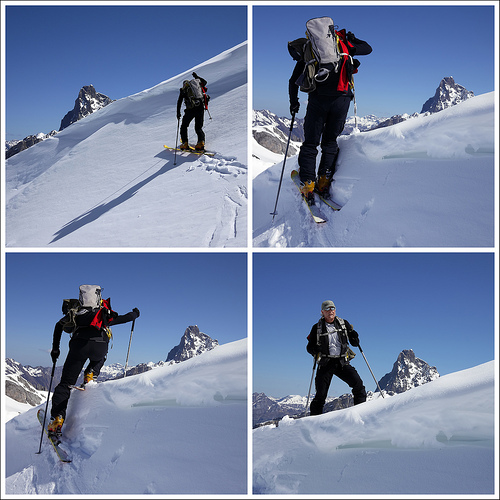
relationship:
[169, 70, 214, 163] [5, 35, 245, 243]
skier on side of mountain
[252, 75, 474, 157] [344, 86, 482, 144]
mountains under patches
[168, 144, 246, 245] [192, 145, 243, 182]
ski marks in snow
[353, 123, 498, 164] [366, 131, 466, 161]
ski marks in snow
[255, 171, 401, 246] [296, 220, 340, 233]
ski marks in snow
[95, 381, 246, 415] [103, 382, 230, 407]
ski marks in snow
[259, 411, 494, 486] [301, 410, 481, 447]
ski marks in snow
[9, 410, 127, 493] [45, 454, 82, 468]
ski marks in snow